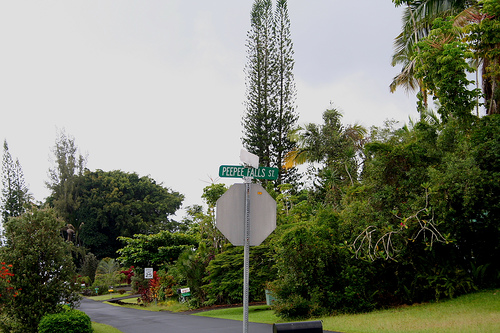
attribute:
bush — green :
[36, 307, 91, 331]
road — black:
[74, 290, 274, 329]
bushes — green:
[279, 126, 497, 323]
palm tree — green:
[473, 4, 498, 116]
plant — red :
[125, 263, 159, 303]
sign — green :
[221, 159, 291, 184]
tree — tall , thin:
[243, 0, 301, 210]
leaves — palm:
[373, 0, 465, 68]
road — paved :
[51, 291, 310, 332]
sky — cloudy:
[75, 43, 188, 147]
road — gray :
[59, 290, 280, 331]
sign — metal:
[141, 264, 157, 281]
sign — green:
[217, 163, 280, 180]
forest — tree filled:
[75, 4, 498, 311]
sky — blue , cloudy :
[6, 5, 241, 159]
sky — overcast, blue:
[4, 1, 431, 203]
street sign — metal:
[219, 163, 280, 182]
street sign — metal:
[213, 182, 281, 251]